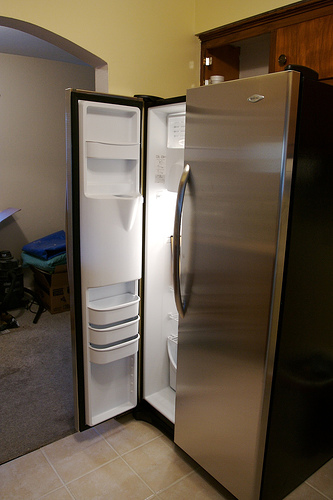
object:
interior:
[82, 103, 171, 425]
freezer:
[60, 79, 188, 433]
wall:
[3, 0, 292, 96]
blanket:
[19, 251, 67, 271]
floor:
[0, 424, 212, 500]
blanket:
[26, 222, 72, 258]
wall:
[17, 59, 101, 236]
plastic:
[79, 102, 137, 413]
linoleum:
[0, 420, 317, 497]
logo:
[246, 93, 265, 102]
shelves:
[79, 98, 142, 307]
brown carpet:
[3, 331, 71, 426]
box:
[27, 254, 72, 316]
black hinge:
[286, 62, 316, 78]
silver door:
[173, 68, 295, 498]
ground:
[206, 63, 215, 103]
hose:
[33, 292, 46, 324]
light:
[151, 189, 175, 237]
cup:
[208, 74, 225, 84]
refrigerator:
[62, 69, 297, 493]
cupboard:
[192, 3, 332, 82]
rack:
[85, 125, 140, 364]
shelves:
[81, 281, 141, 365]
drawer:
[160, 338, 181, 393]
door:
[60, 82, 147, 439]